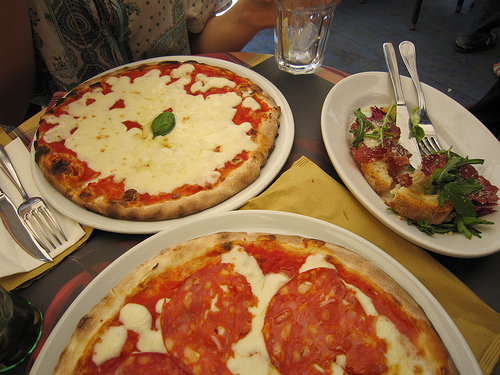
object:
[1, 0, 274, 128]
person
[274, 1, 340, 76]
glass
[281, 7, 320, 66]
ice cubes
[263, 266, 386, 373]
salami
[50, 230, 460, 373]
pizza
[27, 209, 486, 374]
plate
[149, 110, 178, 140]
leaf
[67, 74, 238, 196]
cheese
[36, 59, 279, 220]
pizza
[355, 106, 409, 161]
salami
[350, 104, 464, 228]
bread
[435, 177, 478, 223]
leaves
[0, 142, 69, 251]
fork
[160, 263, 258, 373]
pepperoni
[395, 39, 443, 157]
fork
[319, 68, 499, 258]
plate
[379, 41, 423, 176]
knife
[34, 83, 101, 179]
edge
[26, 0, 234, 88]
shirt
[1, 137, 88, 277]
napkin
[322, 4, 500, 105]
floor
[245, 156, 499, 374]
place mat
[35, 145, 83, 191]
bubbles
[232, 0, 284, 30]
hand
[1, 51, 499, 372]
table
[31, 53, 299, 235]
plate